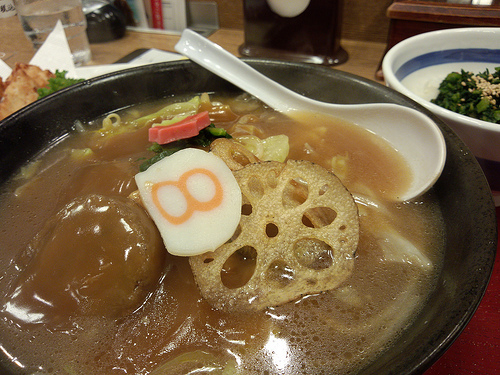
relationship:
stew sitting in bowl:
[2, 89, 447, 371] [2, 52, 498, 374]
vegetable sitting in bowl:
[443, 69, 495, 110] [381, 27, 500, 161]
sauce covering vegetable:
[456, 70, 485, 101] [425, 65, 484, 121]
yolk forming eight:
[158, 177, 217, 217] [150, 168, 221, 224]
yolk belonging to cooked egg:
[158, 177, 217, 217] [121, 141, 250, 260]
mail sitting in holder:
[127, 0, 184, 32] [121, 1, 221, 49]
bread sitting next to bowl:
[0, 61, 55, 121] [2, 52, 498, 374]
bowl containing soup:
[2, 52, 498, 374] [0, 97, 447, 373]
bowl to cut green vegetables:
[2, 59, 498, 375] [430, 60, 499, 121]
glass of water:
[14, 2, 77, 53] [20, 9, 117, 76]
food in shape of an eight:
[0, 64, 498, 372] [150, 167, 225, 224]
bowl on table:
[2, 52, 498, 374] [2, 2, 494, 374]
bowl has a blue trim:
[2, 59, 498, 375] [394, 48, 499, 84]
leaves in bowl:
[432, 63, 493, 100] [381, 27, 500, 161]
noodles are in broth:
[361, 282, 426, 340] [0, 112, 427, 372]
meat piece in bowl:
[23, 194, 163, 323] [2, 52, 498, 374]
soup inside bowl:
[17, 64, 449, 373] [2, 52, 498, 374]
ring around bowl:
[394, 47, 499, 82] [2, 59, 498, 375]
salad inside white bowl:
[420, 32, 499, 115] [376, 8, 498, 166]